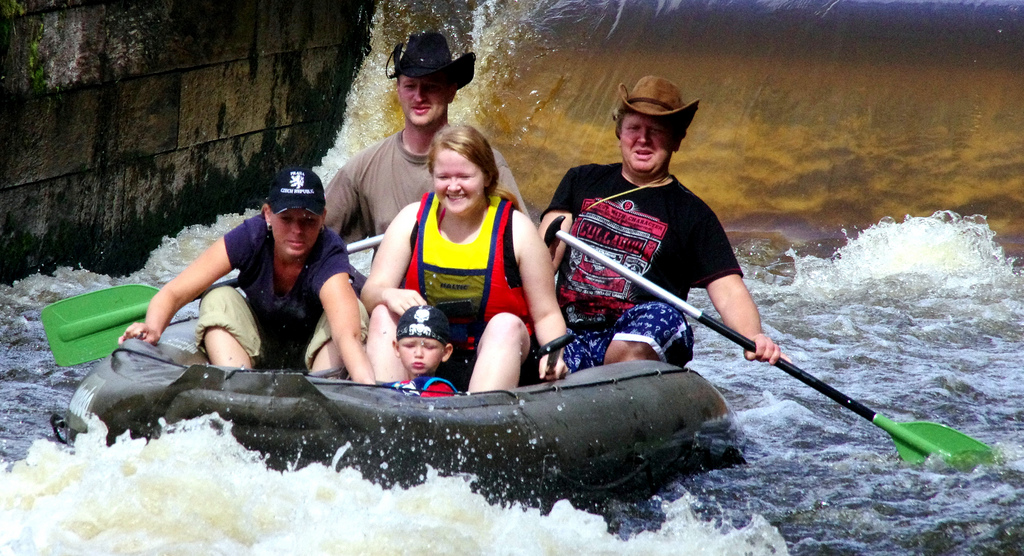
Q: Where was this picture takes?
A: Rafting down the river.